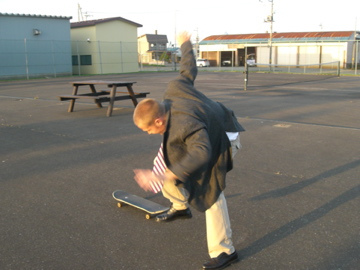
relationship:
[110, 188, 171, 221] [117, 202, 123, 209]
skateboard has wheel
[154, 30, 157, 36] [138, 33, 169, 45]
chimney on roof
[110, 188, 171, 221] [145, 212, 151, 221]
skateboard has wheel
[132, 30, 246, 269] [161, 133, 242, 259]
young boy wearing pants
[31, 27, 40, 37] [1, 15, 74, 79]
light on building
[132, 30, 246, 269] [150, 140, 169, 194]
young boy wearing tie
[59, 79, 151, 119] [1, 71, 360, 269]
table on ground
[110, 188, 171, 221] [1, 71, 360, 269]
skateboard on ground